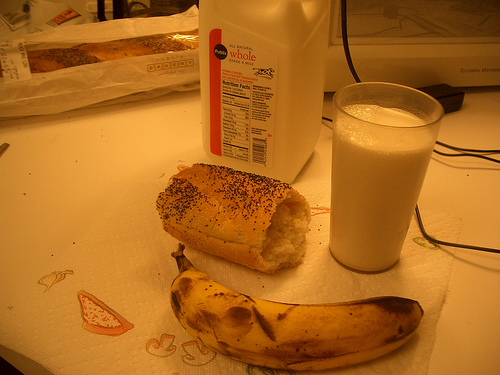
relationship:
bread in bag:
[29, 30, 201, 75] [1, 4, 201, 121]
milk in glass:
[331, 104, 433, 271] [328, 80, 445, 273]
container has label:
[199, 1, 330, 186] [206, 27, 279, 170]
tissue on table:
[1, 158, 464, 374] [1, 85, 498, 372]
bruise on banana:
[250, 303, 277, 342] [168, 244, 424, 373]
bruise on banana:
[224, 306, 253, 337] [168, 244, 424, 373]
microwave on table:
[324, 1, 500, 91] [1, 85, 498, 372]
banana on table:
[168, 244, 424, 373] [1, 85, 498, 372]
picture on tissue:
[78, 288, 134, 338] [1, 158, 464, 374]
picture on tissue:
[146, 334, 176, 359] [1, 158, 464, 374]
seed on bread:
[204, 222, 208, 228] [155, 163, 311, 276]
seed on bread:
[214, 217, 219, 222] [155, 163, 311, 276]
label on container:
[206, 27, 279, 170] [199, 1, 330, 186]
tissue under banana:
[1, 158, 464, 374] [168, 244, 424, 373]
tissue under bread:
[1, 158, 464, 374] [155, 163, 311, 276]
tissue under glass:
[1, 158, 464, 374] [328, 80, 445, 273]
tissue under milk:
[1, 158, 464, 374] [331, 104, 433, 271]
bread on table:
[29, 30, 201, 75] [1, 85, 498, 372]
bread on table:
[155, 163, 311, 276] [1, 85, 498, 372]